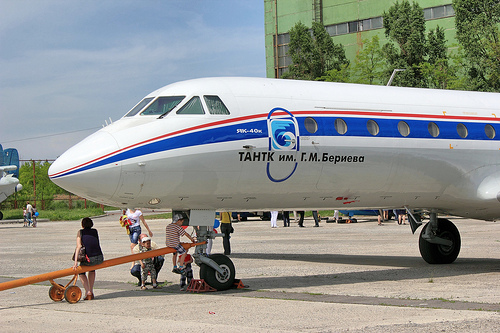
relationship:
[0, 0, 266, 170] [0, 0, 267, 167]
clouds in sky